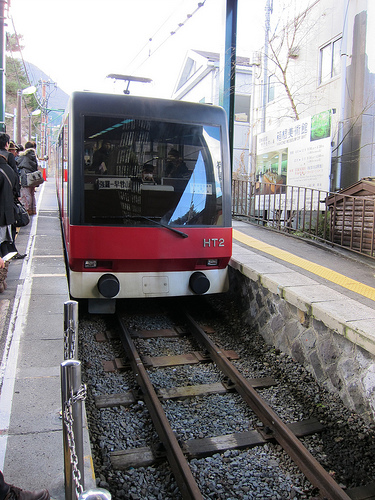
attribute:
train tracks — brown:
[119, 303, 353, 498]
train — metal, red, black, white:
[49, 87, 236, 316]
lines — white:
[23, 195, 43, 426]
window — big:
[75, 110, 232, 229]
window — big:
[82, 116, 226, 226]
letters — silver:
[202, 236, 215, 246]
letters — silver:
[275, 121, 308, 145]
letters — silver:
[258, 135, 276, 147]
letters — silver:
[289, 146, 324, 193]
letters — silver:
[255, 194, 324, 209]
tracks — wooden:
[110, 335, 323, 490]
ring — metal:
[58, 356, 81, 369]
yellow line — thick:
[254, 235, 374, 301]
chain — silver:
[58, 314, 88, 494]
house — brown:
[324, 177, 373, 253]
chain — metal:
[61, 379, 93, 488]